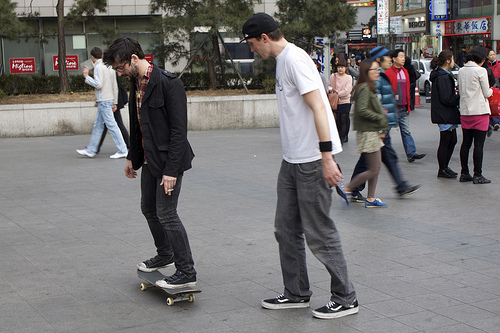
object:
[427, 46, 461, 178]
pedestrian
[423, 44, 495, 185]
group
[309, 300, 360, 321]
sneaker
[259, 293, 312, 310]
sneaker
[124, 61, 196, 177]
jacket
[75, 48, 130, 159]
person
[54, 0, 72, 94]
trunk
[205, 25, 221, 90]
trunk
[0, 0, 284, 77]
building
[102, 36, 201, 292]
male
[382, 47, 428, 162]
man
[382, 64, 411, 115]
coat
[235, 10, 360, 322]
male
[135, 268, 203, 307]
skateboard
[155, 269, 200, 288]
feet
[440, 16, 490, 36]
sign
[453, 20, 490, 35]
writing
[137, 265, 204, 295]
grip tape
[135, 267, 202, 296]
board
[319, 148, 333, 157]
wrist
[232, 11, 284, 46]
hat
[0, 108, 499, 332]
walkway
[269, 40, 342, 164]
shirt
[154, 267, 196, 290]
shoe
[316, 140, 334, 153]
wristband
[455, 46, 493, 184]
woman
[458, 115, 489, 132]
pink skirt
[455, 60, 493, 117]
white coat